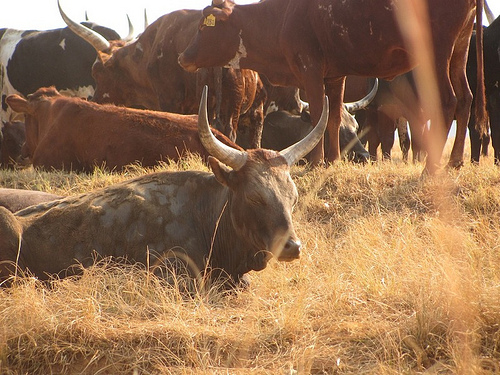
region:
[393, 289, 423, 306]
part of the grass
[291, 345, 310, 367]
part of the plain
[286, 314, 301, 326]
part of a grass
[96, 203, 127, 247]
part of a body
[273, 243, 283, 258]
part of a mouth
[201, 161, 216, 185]
part of a back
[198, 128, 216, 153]
pat of a horn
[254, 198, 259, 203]
eye of a cow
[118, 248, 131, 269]
tail of a cow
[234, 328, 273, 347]
tip of a grass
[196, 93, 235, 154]
horns on the animal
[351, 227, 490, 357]
hay on the ground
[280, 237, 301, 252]
the animals nose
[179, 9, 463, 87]
a brown cow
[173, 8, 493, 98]
the cow is standing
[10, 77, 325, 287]
the cow is laying down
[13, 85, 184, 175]
a cow on the ground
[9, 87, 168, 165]
cow is brown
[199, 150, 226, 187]
the cows ear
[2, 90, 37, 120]
the cow has an ear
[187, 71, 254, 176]
horn on a cow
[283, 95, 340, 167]
horn on a cow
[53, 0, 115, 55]
horn on a cow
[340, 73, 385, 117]
horn on a cow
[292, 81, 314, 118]
horn on a cow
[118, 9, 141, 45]
horn on a cow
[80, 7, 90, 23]
horn on a cow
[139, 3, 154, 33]
horn on a cow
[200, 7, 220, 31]
yellow tag on a cow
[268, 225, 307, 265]
nose of a cow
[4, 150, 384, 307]
bull laying on ground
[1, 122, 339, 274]
bull with spots on back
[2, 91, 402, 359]
bull with horns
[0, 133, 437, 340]
bull laying in dead grass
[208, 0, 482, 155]
brown and white cow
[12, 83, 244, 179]
brown cow laying down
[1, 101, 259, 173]
brown cow laying in dead grass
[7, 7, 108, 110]
black and white cow standing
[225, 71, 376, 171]
black and white bull with horns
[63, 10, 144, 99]
bull with horns standing with cows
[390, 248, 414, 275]
part of the grass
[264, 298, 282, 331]
part of the plain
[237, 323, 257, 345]
tip of a grass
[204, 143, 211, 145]
part of a horn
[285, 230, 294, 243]
mouth of a cow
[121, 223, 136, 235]
body of a cow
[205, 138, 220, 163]
horn of a cow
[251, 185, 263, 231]
eye of a cow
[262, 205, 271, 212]
head of a cow